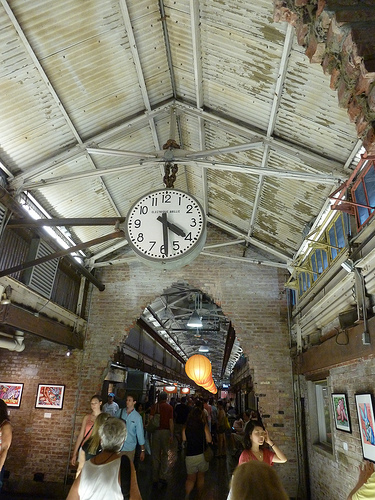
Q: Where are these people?
A: An art gallery.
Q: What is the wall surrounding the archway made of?
A: Brick.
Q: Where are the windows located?
A: At the top of the wall.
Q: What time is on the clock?
A: 4:30.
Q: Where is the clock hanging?
A: From ceiling.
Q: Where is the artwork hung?
A: On brick walls.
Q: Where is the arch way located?
A: In center of brick wall.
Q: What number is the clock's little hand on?
A: 4.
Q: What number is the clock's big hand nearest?
A: 6.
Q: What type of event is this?
A: Art gallery show.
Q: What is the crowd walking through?
A: Tunnel.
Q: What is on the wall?
A: Pictures.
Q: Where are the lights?
A: Ceiling.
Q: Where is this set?
A: The train station.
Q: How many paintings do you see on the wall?
A: 4.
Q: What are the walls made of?
A: Brick.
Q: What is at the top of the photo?
A: A clock.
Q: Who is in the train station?
A: Tourists.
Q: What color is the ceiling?
A: White.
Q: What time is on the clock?
A: 4:30.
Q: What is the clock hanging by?
A: A chain.